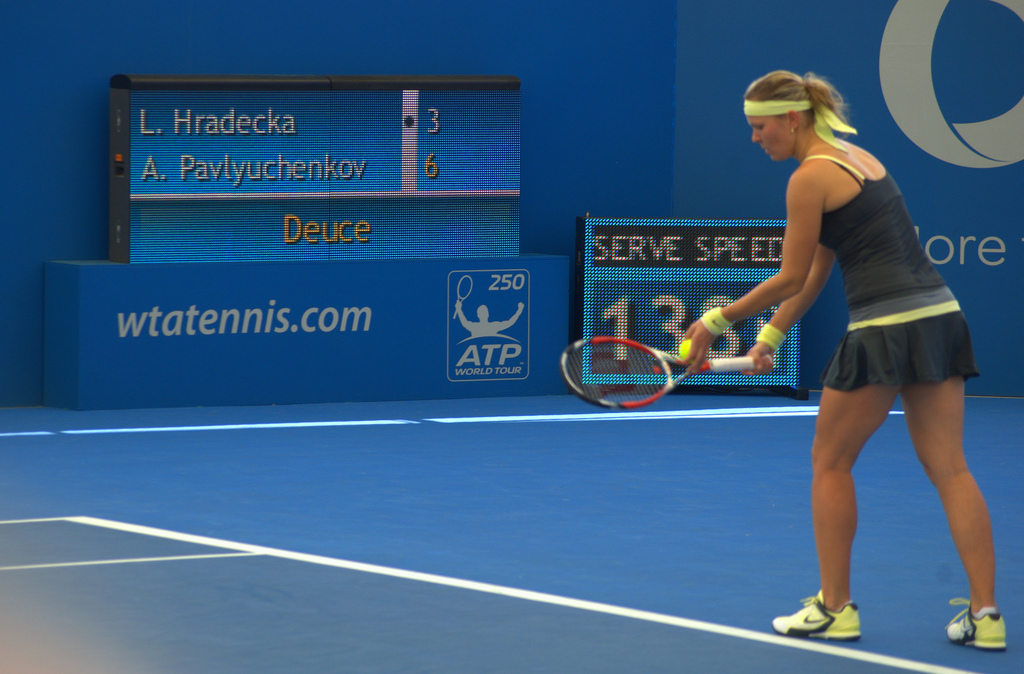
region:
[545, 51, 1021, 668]
tennis player ready to serve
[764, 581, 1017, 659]
tennis shoes are green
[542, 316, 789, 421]
a racket color red and white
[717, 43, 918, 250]
the woman is blonde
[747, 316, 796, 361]
headband on the wrist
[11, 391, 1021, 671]
the floor is color blue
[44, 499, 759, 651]
the line is white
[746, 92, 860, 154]
Yellow tied headband on a woman.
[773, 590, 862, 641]
A woman's left Nike sneaker.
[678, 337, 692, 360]
A yellow tennis ball.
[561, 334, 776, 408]
A red, grey and black racket with white handle.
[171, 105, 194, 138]
Grey H in Hradecka.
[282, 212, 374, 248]
Orange lettered word Deuce.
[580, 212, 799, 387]
Blue and black sign that says SERVE SPEED in white.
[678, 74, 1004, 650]
Brown haired tennis player in a black skirt.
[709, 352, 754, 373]
White wrapped tennis racket handle.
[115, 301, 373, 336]
wtatennis.com in grey lettering.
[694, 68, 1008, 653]
a smoking hot woman playing tennis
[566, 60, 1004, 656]
a smoking hot woman holding shaft and ball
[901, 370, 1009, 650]
right leg of a smoking hot woman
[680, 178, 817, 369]
left arm of a smoking hot woman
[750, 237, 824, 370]
right arm of a smoking hot woman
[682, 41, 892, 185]
head of a woman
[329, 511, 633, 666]
white line on ground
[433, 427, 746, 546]
blue court under lady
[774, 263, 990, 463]
skirt on the lady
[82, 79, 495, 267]
score on the scoreboard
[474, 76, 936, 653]
woman looking at a ball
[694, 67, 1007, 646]
A tennis player on a court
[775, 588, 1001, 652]
Yellow and white shoes on a player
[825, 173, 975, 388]
A black tennis outfit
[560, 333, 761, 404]
A tennis racket in a woman's hand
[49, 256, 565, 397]
A blue wall near a tennis court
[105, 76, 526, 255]
A sign on a wall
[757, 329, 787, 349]
A yellow wrist band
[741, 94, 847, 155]
A yellow head band on a woman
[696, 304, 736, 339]
A yellow band on a wrist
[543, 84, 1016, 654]
A woman playing tennis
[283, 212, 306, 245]
A letter on a sign.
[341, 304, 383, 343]
A letter on a sign.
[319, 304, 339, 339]
A letter on a sign.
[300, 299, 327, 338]
A letter on a sign.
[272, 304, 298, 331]
A letter on a sign.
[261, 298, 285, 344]
A letter on a sign.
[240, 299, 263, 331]
A letter on a sign.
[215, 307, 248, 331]
A letter on a sign.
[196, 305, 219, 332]
A letter on a sign.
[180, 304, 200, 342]
A letter on a sign.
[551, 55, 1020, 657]
A woman playing tennis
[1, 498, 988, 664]
White lines on the tennis court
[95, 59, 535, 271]
A rectangular screen scoreboard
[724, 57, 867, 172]
Yellow headband around woman's head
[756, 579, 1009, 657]
A pair of sneakers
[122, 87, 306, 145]
"L. Hradecka" written on scoreboard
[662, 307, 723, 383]
A tennis ball in a hand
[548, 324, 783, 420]
A tennis racket in the hand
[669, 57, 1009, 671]
woman playing tennis match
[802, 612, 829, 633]
Nike logo on shoe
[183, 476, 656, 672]
white line on the tennis court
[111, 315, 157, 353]
white letter on the wall